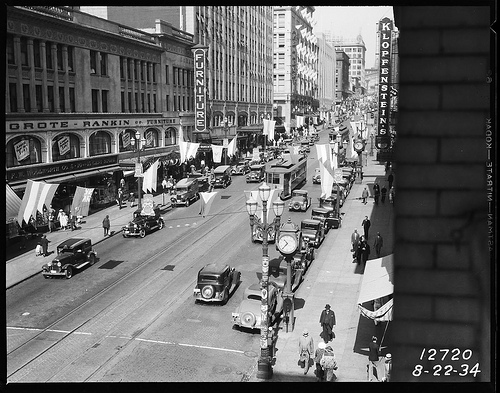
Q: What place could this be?
A: It is a road.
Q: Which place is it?
A: It is a road.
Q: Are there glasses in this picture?
A: No, there are no glasses.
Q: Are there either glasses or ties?
A: No, there are no glasses or ties.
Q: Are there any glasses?
A: No, there are no glasses.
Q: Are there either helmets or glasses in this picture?
A: No, there are no glasses or helmets.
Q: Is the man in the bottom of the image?
A: Yes, the man is in the bottom of the image.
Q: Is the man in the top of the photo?
A: No, the man is in the bottom of the image.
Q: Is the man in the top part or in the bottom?
A: The man is in the bottom of the image.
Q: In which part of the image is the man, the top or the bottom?
A: The man is in the bottom of the image.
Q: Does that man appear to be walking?
A: Yes, the man is walking.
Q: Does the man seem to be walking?
A: Yes, the man is walking.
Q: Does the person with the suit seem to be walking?
A: Yes, the man is walking.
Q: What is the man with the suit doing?
A: The man is walking.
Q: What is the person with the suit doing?
A: The man is walking.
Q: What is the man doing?
A: The man is walking.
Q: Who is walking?
A: The man is walking.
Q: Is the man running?
A: No, the man is walking.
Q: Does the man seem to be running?
A: No, the man is walking.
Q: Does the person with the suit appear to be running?
A: No, the man is walking.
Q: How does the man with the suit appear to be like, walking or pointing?
A: The man is walking.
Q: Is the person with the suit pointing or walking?
A: The man is walking.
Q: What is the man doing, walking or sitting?
A: The man is walking.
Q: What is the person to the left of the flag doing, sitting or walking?
A: The man is walking.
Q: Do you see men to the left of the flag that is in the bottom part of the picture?
A: Yes, there is a man to the left of the flag.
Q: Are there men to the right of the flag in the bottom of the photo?
A: No, the man is to the left of the flag.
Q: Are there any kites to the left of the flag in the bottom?
A: No, there is a man to the left of the flag.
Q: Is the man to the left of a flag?
A: Yes, the man is to the left of a flag.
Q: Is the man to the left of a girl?
A: No, the man is to the left of a flag.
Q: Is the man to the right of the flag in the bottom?
A: No, the man is to the left of the flag.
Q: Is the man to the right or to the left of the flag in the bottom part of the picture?
A: The man is to the left of the flag.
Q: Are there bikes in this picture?
A: No, there are no bikes.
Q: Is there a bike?
A: No, there are no bikes.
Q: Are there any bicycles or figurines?
A: No, there are no bicycles or figurines.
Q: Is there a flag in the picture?
A: Yes, there is a flag.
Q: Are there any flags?
A: Yes, there is a flag.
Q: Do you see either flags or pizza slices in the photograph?
A: Yes, there is a flag.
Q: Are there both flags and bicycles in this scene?
A: No, there is a flag but no bicycles.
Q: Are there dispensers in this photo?
A: No, there are no dispensers.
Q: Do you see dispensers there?
A: No, there are no dispensers.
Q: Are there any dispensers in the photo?
A: No, there are no dispensers.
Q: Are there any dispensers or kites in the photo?
A: No, there are no dispensers or kites.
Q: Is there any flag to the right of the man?
A: Yes, there is a flag to the right of the man.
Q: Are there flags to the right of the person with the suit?
A: Yes, there is a flag to the right of the man.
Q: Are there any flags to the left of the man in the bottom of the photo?
A: No, the flag is to the right of the man.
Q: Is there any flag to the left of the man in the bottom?
A: No, the flag is to the right of the man.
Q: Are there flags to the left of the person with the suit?
A: No, the flag is to the right of the man.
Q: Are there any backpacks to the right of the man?
A: No, there is a flag to the right of the man.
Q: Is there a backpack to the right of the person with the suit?
A: No, there is a flag to the right of the man.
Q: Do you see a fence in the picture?
A: No, there are no fences.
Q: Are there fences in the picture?
A: No, there are no fences.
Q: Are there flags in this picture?
A: Yes, there is a flag.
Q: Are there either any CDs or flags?
A: Yes, there is a flag.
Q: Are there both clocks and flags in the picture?
A: Yes, there are both a flag and a clock.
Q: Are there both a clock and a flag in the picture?
A: Yes, there are both a flag and a clock.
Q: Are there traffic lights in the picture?
A: No, there are no traffic lights.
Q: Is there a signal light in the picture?
A: No, there are no traffic lights.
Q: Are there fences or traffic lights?
A: No, there are no traffic lights or fences.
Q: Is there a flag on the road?
A: Yes, there is a flag on the road.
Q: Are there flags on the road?
A: Yes, there is a flag on the road.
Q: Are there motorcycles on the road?
A: No, there is a flag on the road.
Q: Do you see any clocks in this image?
A: Yes, there is a clock.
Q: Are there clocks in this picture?
A: Yes, there is a clock.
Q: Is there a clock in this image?
A: Yes, there is a clock.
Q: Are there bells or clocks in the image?
A: Yes, there is a clock.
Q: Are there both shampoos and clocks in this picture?
A: No, there is a clock but no shampoos.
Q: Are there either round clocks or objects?
A: Yes, there is a round clock.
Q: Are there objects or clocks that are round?
A: Yes, the clock is round.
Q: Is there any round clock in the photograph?
A: Yes, there is a round clock.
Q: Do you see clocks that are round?
A: Yes, there is a round clock.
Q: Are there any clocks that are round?
A: Yes, there is a clock that is round.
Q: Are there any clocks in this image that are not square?
A: Yes, there is a round clock.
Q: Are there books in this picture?
A: No, there are no books.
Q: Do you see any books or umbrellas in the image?
A: No, there are no books or umbrellas.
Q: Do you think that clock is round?
A: Yes, the clock is round.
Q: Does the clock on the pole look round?
A: Yes, the clock is round.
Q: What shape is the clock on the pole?
A: The clock is round.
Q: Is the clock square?
A: No, the clock is round.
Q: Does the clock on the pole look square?
A: No, the clock is round.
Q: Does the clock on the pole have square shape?
A: No, the clock is round.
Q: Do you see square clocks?
A: No, there is a clock but it is round.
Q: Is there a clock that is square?
A: No, there is a clock but it is round.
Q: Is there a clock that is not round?
A: No, there is a clock but it is round.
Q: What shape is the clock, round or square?
A: The clock is round.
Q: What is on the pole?
A: The clock is on the pole.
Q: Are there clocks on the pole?
A: Yes, there is a clock on the pole.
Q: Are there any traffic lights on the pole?
A: No, there is a clock on the pole.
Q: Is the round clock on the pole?
A: Yes, the clock is on the pole.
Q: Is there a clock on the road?
A: Yes, there is a clock on the road.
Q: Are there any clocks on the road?
A: Yes, there is a clock on the road.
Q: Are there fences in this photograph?
A: No, there are no fences.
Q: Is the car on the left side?
A: Yes, the car is on the left of the image.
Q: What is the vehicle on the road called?
A: The vehicle is a car.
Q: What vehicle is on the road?
A: The vehicle is a car.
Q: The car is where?
A: The car is on the road.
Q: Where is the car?
A: The car is on the road.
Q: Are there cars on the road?
A: Yes, there is a car on the road.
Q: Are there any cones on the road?
A: No, there is a car on the road.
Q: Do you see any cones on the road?
A: No, there is a car on the road.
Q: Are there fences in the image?
A: No, there are no fences.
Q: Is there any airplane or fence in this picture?
A: No, there are no fences or airplanes.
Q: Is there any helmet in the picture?
A: No, there are no helmets.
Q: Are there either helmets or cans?
A: No, there are no helmets or cans.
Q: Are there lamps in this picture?
A: Yes, there is a lamp.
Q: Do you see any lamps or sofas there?
A: Yes, there is a lamp.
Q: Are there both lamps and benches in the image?
A: No, there is a lamp but no benches.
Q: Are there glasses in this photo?
A: No, there are no glasses.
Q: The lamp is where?
A: The lamp is on the road.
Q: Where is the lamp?
A: The lamp is on the road.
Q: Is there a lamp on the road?
A: Yes, there is a lamp on the road.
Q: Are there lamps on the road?
A: Yes, there is a lamp on the road.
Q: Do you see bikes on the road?
A: No, there is a lamp on the road.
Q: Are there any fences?
A: No, there are no fences.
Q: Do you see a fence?
A: No, there are no fences.